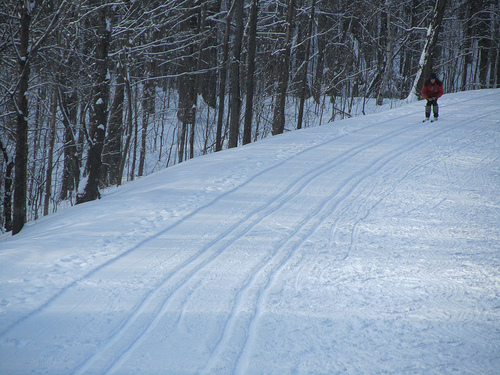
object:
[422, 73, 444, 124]
person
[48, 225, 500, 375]
snow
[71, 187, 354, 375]
lines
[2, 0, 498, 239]
trees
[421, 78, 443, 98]
jacket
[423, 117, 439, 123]
skis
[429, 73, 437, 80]
hat